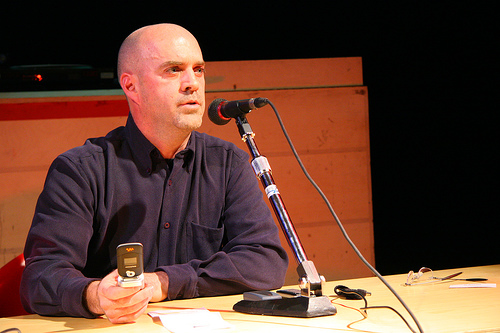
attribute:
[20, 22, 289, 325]
man — sitting, speaking, bald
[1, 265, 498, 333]
table — wooden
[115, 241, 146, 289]
cell phone — black, silver, open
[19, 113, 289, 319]
shirt — purple, dark, dark grey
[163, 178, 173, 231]
buttons — dark grey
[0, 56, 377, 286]
bench — brown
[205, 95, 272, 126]
microphone — black, red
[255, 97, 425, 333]
cord — black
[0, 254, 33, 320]
chair — red, hard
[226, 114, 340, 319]
metal stand — black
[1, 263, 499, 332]
desk — wooden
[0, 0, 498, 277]
black stage — dark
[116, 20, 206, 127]
head — shaved